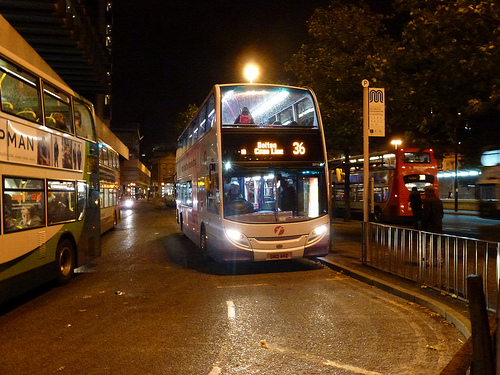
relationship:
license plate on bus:
[258, 244, 304, 263] [145, 61, 348, 270]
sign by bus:
[356, 75, 393, 252] [330, 147, 445, 229]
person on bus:
[231, 105, 261, 125] [172, 77, 332, 259]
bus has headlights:
[0, 47, 103, 284] [223, 223, 328, 245]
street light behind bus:
[222, 37, 294, 121] [126, 64, 376, 316]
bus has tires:
[0, 47, 103, 284] [48, 229, 102, 279]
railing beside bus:
[357, 217, 498, 314] [171, 76, 333, 277]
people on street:
[420, 185, 445, 265] [0, 197, 464, 373]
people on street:
[406, 184, 422, 229] [0, 197, 464, 373]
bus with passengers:
[4, 17, 103, 289] [6, 79, 92, 231]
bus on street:
[317, 147, 442, 221] [0, 197, 464, 373]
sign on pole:
[366, 86, 386, 138] [358, 80, 372, 276]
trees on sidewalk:
[281, 2, 496, 148] [319, 197, 499, 339]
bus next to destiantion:
[172, 77, 332, 259] [236, 130, 315, 161]